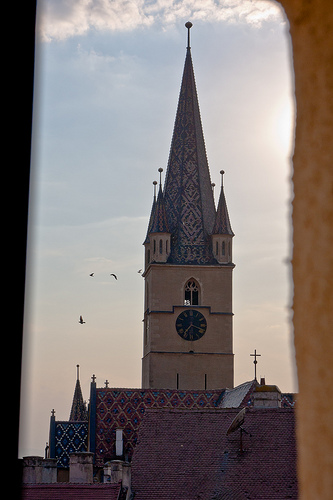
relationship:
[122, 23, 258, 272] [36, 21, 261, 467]
top of building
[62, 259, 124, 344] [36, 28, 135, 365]
birds in sky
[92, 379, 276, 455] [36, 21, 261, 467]
roof of building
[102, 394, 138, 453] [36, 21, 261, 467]
pattern on building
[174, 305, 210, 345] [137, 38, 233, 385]
clock on tower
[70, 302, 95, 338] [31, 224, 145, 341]
bird in air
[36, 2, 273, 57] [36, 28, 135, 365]
clouds in sky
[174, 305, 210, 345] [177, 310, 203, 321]
clock has gold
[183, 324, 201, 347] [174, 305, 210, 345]
hands on clock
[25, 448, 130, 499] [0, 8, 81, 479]
chimneys on left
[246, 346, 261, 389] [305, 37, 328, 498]
cross to right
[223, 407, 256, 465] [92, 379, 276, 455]
satellite dish on roof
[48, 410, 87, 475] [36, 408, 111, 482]
blue diamond roof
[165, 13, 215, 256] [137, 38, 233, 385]
steeple on tower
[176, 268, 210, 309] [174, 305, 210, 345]
window over clock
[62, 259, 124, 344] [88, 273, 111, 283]
birds flying close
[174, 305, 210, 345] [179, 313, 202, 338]
clock has face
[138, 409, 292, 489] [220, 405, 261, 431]
roof with dish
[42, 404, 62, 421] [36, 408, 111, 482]
cross on building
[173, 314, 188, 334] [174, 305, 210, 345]
numerals on clock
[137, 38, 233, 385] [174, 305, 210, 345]
tower has clock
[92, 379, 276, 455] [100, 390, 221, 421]
roof has mosaic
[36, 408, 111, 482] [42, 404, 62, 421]
roof has cross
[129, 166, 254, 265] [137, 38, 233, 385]
spires on tower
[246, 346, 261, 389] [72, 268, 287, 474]
cross on church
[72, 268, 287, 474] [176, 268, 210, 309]
church has window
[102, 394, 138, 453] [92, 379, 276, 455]
pattern on roof